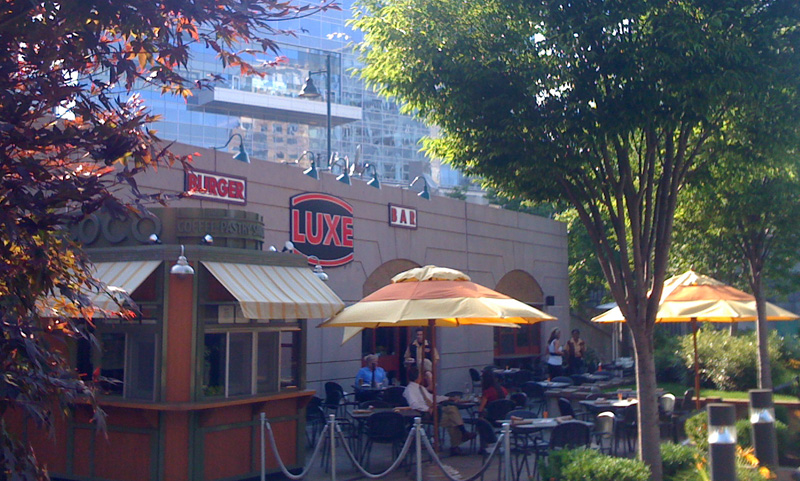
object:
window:
[382, 113, 402, 130]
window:
[288, 123, 300, 135]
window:
[165, 100, 179, 122]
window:
[383, 161, 397, 179]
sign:
[387, 202, 419, 231]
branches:
[649, 133, 691, 324]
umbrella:
[591, 268, 799, 325]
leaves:
[202, 30, 294, 80]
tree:
[673, 0, 798, 481]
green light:
[208, 132, 250, 164]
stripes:
[258, 264, 316, 320]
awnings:
[26, 260, 166, 319]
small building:
[0, 204, 348, 481]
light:
[296, 70, 321, 98]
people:
[354, 354, 388, 392]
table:
[347, 404, 424, 426]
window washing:
[196, 74, 364, 127]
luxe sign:
[288, 191, 356, 270]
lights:
[281, 149, 322, 182]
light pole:
[324, 53, 333, 172]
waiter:
[403, 328, 441, 381]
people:
[546, 326, 568, 380]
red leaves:
[70, 93, 165, 149]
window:
[192, 332, 230, 401]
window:
[224, 326, 253, 403]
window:
[254, 332, 279, 393]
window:
[278, 330, 305, 392]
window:
[124, 329, 166, 404]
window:
[104, 328, 125, 394]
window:
[494, 304, 542, 356]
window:
[381, 146, 402, 163]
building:
[26, 0, 506, 205]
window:
[190, 124, 205, 137]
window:
[242, 123, 253, 131]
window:
[275, 150, 285, 160]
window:
[363, 122, 383, 144]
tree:
[324, 0, 774, 481]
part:
[553, 0, 800, 212]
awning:
[199, 259, 345, 321]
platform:
[196, 85, 364, 130]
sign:
[179, 166, 247, 206]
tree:
[1, 0, 348, 477]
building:
[0, 109, 575, 481]